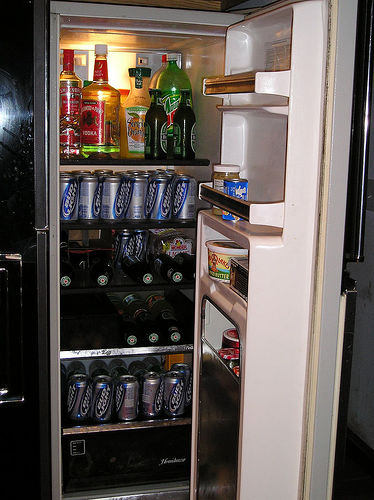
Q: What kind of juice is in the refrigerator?
A: Orange.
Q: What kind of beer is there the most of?
A: Bud Light.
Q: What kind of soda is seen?
A: Mountain Dew.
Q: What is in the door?
A: Condiments.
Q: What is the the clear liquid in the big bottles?
A: Vodka.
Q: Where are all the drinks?
A: In the refrigerator.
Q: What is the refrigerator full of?
A: Drinks.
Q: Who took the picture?
A: Photographer.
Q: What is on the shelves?
A: Beer.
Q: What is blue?
A: The cans on the third shelf.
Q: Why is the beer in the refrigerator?
A: To keep it cold.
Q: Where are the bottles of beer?
A: On the second shelf.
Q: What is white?
A: The refrigerator.